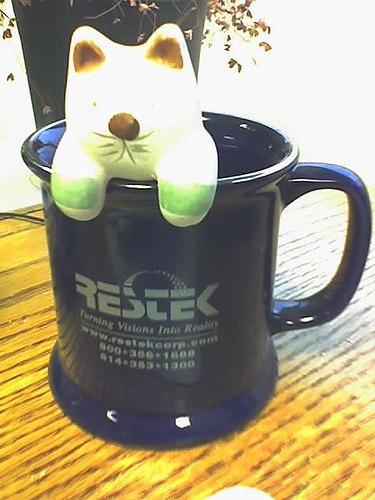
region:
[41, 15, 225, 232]
cat hanging over cup rim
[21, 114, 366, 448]
blue mug with company information and philosophy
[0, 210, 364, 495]
wooden surface with brown and yellow lines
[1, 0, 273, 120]
tiny leaves and stems hanging over planter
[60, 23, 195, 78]
white and brown cat ears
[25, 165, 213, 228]
green and white front paws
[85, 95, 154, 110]
dots for eyes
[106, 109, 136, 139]
brown oval nose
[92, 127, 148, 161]
whiskers pointing sideways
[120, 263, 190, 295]
curved lines and dots over letters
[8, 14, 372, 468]
a cat in a cup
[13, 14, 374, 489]
a cat in a coffee mug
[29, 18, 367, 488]
a cat in a black cup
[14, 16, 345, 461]
a cat in a black coffee mug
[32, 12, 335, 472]
a cat in a black mug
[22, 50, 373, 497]
a coffee mug on a table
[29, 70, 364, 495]
a mug on a table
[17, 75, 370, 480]
a black coffee mug on a table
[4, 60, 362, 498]
a black mug on a table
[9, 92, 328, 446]
a black coffee mug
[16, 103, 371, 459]
a blue cup over a table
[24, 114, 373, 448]
cup has a handle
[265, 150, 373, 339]
handle of cup is blue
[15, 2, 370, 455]
cat of ceramic inside a blue cup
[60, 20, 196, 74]
ears of cat are brown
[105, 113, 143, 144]
nose of cat is brown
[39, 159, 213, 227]
front legs of cat are green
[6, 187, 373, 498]
a brown table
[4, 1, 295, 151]
a black vase behind a blue cup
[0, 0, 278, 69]
vase has small leaves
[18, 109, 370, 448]
a blue mug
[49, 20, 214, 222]
a ceramic cat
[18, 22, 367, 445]
a white ceramic cat in a blug mug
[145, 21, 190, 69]
the cat ear nearest to the mug handle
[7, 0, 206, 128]
a black vase behind the mug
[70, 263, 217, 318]
the large letters in gray on the mug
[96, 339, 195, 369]
the phone numbers on the mug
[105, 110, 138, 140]
the brown nose on the cat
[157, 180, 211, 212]
cat's green paw nearest the handle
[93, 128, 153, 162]
the whiskers and mouth on the cat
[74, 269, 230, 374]
writing on a cup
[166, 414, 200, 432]
a reflection on the cup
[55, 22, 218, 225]
a white cat hanging over a cup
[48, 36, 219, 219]
A white cat with brown ears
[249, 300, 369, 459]
a wood table under the cup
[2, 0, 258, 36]
a vase with flowers in it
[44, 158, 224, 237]
cat paws over a cup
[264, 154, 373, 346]
a handle ona cup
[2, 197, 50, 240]
a wire behind the cup